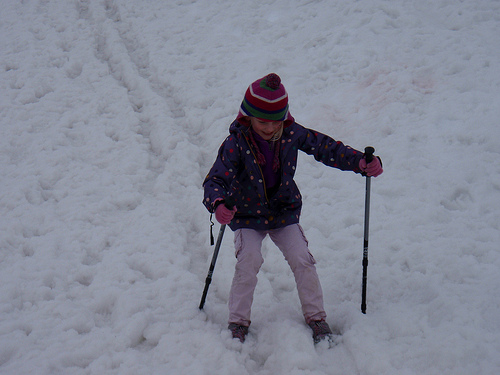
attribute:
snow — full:
[30, 155, 166, 352]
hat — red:
[210, 72, 291, 132]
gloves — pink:
[212, 200, 233, 224]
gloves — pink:
[355, 153, 382, 179]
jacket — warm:
[236, 163, 286, 200]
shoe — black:
[307, 319, 334, 349]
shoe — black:
[226, 320, 248, 345]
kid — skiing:
[184, 53, 408, 355]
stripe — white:
[247, 81, 287, 103]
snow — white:
[48, 230, 168, 369]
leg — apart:
[271, 225, 328, 322]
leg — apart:
[228, 224, 260, 335]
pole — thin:
[358, 120, 378, 320]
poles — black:
[171, 139, 393, 325]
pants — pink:
[221, 221, 328, 326]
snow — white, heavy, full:
[0, 0, 497, 371]